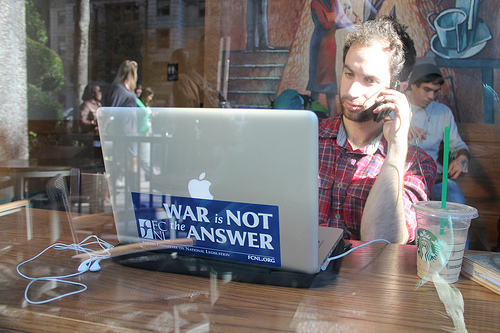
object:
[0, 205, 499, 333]
table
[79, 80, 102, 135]
woman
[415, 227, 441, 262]
logo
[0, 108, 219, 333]
reflection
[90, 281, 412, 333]
wood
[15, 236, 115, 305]
headphones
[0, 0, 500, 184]
ground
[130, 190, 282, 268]
sticker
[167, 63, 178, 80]
sign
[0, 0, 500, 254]
wall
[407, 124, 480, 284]
cup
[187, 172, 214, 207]
logo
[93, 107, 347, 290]
computer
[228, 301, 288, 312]
grain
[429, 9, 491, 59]
cup painting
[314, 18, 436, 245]
man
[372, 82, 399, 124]
phone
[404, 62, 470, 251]
man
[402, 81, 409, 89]
ear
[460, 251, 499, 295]
book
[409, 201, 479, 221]
lid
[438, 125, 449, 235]
straw